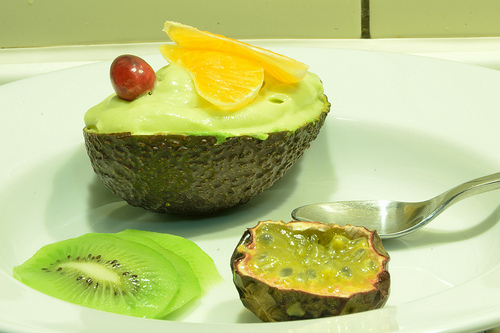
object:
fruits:
[83, 61, 386, 306]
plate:
[341, 43, 492, 329]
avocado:
[102, 92, 341, 192]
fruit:
[181, 20, 287, 95]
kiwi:
[46, 225, 213, 317]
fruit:
[235, 215, 392, 317]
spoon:
[313, 188, 485, 220]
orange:
[176, 30, 287, 100]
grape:
[101, 50, 158, 99]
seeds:
[270, 257, 369, 276]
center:
[269, 224, 377, 286]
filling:
[283, 274, 387, 302]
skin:
[247, 291, 345, 319]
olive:
[97, 57, 148, 96]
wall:
[95, 1, 497, 46]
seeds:
[63, 262, 132, 291]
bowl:
[370, 57, 499, 275]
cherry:
[115, 61, 158, 91]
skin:
[121, 139, 306, 193]